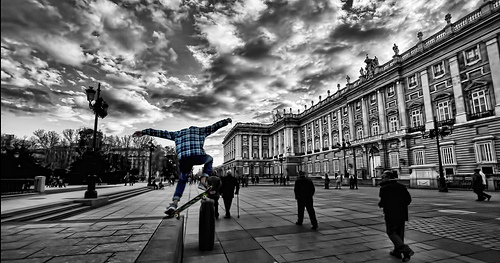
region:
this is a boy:
[145, 117, 230, 215]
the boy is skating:
[143, 98, 228, 214]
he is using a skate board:
[161, 185, 213, 223]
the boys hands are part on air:
[128, 112, 233, 143]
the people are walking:
[277, 170, 408, 239]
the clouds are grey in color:
[1, 3, 355, 72]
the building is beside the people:
[249, 126, 497, 166]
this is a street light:
[78, 88, 113, 205]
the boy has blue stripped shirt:
[176, 130, 203, 154]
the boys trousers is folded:
[201, 172, 211, 177]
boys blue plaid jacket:
[127, 80, 245, 182]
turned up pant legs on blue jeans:
[135, 151, 247, 211]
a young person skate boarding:
[111, 115, 251, 223]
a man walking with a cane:
[220, 152, 245, 227]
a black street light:
[65, 69, 110, 208]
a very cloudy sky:
[14, 6, 310, 110]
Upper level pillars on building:
[341, 93, 435, 146]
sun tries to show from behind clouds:
[155, 34, 342, 136]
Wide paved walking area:
[245, 179, 420, 256]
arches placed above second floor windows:
[361, 96, 422, 137]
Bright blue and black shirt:
[132, 114, 234, 217]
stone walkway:
[50, 220, 119, 261]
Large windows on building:
[429, 94, 456, 123]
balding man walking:
[375, 170, 417, 260]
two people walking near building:
[468, 165, 493, 204]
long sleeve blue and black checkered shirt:
[136, 115, 231, 158]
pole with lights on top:
[80, 75, 108, 199]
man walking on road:
[289, 170, 318, 229]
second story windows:
[465, 82, 495, 115]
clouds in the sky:
[200, 49, 270, 96]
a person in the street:
[288, 162, 325, 227]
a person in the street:
[123, 100, 230, 208]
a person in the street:
[370, 161, 425, 253]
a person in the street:
[321, 165, 331, 187]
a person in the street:
[331, 169, 341, 189]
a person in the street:
[472, 160, 495, 205]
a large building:
[218, 6, 498, 194]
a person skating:
[129, 111, 236, 225]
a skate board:
[160, 183, 222, 217]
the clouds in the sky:
[0, 0, 439, 144]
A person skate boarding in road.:
[114, 95, 256, 258]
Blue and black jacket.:
[125, 101, 256, 163]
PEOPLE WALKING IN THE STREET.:
[212, 154, 427, 261]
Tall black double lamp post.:
[33, 59, 120, 226]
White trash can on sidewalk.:
[17, 162, 48, 203]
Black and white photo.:
[224, 67, 499, 240]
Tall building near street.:
[222, 51, 479, 221]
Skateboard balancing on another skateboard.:
[148, 193, 244, 255]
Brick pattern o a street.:
[4, 204, 131, 261]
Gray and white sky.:
[143, 60, 305, 113]